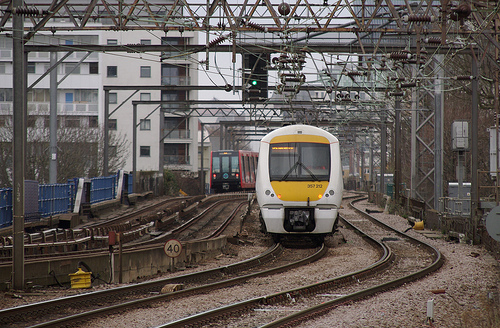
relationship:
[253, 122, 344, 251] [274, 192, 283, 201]
train has a head light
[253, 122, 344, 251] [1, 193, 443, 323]
train on railroad track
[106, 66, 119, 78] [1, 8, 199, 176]
window on building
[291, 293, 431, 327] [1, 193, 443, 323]
gravel next to railroad track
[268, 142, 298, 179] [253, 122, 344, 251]
window on train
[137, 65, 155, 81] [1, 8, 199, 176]
window in building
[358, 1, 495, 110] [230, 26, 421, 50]
building has a walkway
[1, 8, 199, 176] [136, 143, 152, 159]
building has a window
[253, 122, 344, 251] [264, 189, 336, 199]
train has lights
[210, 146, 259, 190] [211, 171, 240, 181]
train has lights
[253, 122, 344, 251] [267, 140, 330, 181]
train has a windshield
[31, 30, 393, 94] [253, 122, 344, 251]
electric wires are above train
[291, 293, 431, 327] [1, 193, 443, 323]
gravel between railroad track